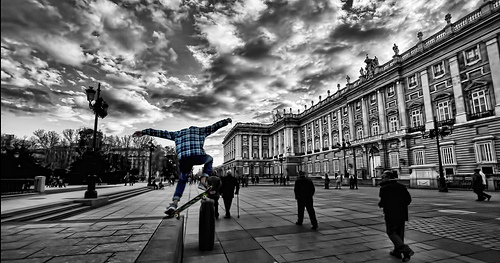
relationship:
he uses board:
[135, 116, 234, 219] [167, 179, 225, 215]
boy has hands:
[135, 116, 234, 219] [133, 116, 233, 136]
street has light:
[188, 157, 500, 262] [428, 124, 452, 192]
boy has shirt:
[135, 116, 234, 219] [128, 109, 241, 159]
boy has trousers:
[135, 116, 234, 219] [166, 156, 210, 204]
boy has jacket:
[135, 116, 234, 219] [128, 109, 241, 159]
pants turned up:
[166, 156, 210, 204] [169, 171, 211, 201]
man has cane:
[222, 167, 240, 221] [235, 192, 239, 226]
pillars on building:
[265, 36, 495, 155] [221, 2, 497, 185]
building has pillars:
[221, 2, 497, 185] [265, 36, 495, 155]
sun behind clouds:
[152, 31, 219, 93] [0, 3, 492, 142]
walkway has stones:
[188, 157, 500, 262] [254, 214, 495, 261]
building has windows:
[221, 2, 497, 185] [301, 83, 499, 154]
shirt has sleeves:
[128, 109, 241, 159] [133, 116, 233, 136]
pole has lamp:
[81, 85, 106, 197] [85, 86, 110, 115]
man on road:
[288, 171, 320, 229] [188, 157, 500, 262]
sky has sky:
[0, 3, 492, 142] [0, 3, 492, 142]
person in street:
[288, 171, 320, 229] [188, 157, 500, 262]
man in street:
[288, 171, 320, 229] [188, 157, 500, 262]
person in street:
[222, 167, 240, 221] [188, 157, 500, 262]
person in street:
[319, 175, 333, 191] [188, 157, 500, 262]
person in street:
[337, 175, 344, 186] [188, 157, 500, 262]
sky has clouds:
[0, 3, 492, 142] [0, 3, 492, 142]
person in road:
[135, 116, 234, 219] [188, 157, 500, 262]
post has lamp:
[81, 85, 106, 197] [85, 89, 108, 115]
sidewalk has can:
[3, 143, 189, 259] [36, 174, 46, 196]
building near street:
[221, 2, 497, 185] [188, 157, 500, 262]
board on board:
[167, 179, 225, 215] [196, 203, 220, 252]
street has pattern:
[188, 157, 500, 262] [254, 214, 495, 261]